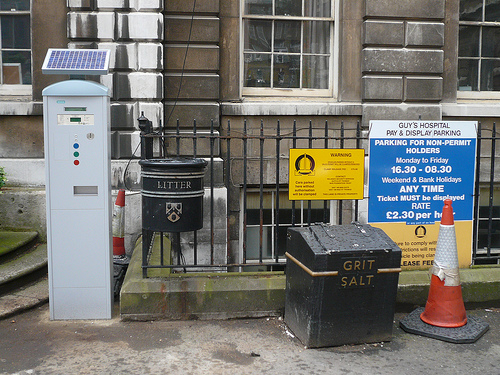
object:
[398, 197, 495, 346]
safety cone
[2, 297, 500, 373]
sidewalk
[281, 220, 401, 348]
salt box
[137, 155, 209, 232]
litter bin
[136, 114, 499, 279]
fence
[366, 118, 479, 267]
sign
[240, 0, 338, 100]
window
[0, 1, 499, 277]
building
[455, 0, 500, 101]
window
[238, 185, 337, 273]
window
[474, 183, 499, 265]
window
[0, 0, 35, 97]
window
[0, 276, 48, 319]
steps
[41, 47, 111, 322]
ticket meter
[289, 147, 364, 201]
sign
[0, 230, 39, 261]
step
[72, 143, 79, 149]
button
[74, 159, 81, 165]
button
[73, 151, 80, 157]
button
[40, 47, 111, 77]
solar power panel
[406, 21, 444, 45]
brick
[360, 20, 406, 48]
brick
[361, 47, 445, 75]
brick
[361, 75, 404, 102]
brick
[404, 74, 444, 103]
brick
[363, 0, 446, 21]
brick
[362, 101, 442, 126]
brick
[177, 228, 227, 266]
brick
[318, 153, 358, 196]
black lettering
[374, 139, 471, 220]
white lettering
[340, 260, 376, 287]
gold lettering